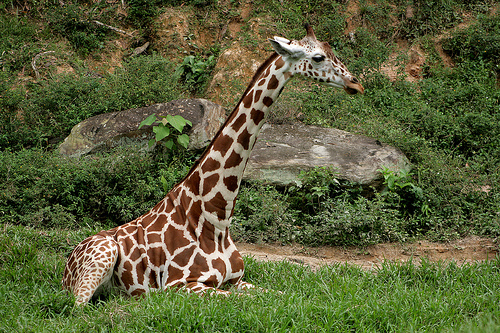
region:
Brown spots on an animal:
[122, 254, 149, 292]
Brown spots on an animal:
[140, 239, 177, 271]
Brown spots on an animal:
[157, 219, 205, 259]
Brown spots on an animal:
[168, 245, 212, 274]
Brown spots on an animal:
[194, 154, 239, 210]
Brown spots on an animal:
[233, 104, 275, 131]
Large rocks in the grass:
[51, 80, 407, 225]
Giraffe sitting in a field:
[29, 22, 406, 330]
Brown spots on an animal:
[284, 36, 359, 96]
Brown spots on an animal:
[62, 234, 124, 284]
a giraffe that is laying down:
[56, 23, 366, 314]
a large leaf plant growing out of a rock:
[142, 110, 206, 162]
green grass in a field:
[6, 233, 496, 331]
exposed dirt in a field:
[243, 236, 495, 269]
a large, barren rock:
[54, 96, 415, 186]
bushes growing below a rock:
[3, 168, 498, 233]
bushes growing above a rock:
[306, 88, 465, 147]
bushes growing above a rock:
[13, 58, 221, 88]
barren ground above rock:
[146, 7, 343, 89]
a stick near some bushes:
[68, 15, 141, 43]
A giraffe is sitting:
[34, 99, 396, 299]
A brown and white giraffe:
[60, 195, 352, 322]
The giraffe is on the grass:
[45, 208, 384, 320]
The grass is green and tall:
[45, 250, 215, 330]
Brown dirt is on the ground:
[230, 207, 497, 295]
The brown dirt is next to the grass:
[253, 218, 491, 303]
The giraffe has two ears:
[12, 33, 317, 285]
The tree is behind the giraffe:
[71, 83, 442, 244]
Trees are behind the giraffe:
[24, 8, 278, 85]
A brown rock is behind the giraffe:
[267, 122, 409, 239]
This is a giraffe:
[87, 61, 427, 326]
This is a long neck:
[142, 56, 292, 228]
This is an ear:
[261, 47, 326, 79]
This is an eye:
[273, 55, 343, 81]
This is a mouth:
[321, 76, 358, 98]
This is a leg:
[43, 232, 168, 313]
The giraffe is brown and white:
[170, 58, 242, 190]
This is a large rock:
[308, 134, 372, 193]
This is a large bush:
[359, 28, 468, 178]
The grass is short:
[285, 299, 300, 319]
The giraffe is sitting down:
[43, 135, 296, 322]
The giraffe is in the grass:
[88, 34, 345, 309]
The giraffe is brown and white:
[62, 79, 294, 309]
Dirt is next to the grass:
[264, 215, 481, 264]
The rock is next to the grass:
[281, 113, 455, 287]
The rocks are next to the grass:
[81, 18, 296, 125]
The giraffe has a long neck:
[227, 2, 476, 165]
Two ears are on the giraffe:
[259, 21, 384, 122]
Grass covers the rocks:
[13, 2, 205, 172]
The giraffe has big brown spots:
[102, 189, 295, 314]